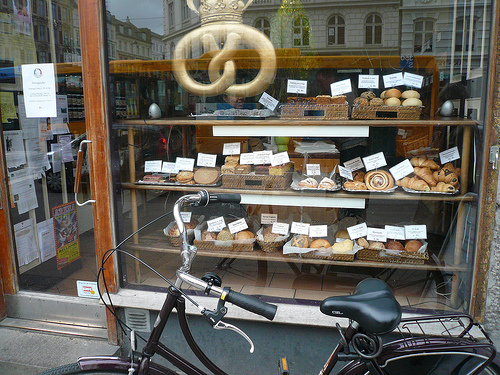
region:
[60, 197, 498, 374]
A bicycle parked in front of the window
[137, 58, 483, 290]
A display of baked goods in the window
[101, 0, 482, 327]
A glass window in front of the baked goods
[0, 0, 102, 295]
A large glass door by the bike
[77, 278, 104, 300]
A small white tag on the door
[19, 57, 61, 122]
A white paper hanging on the glass door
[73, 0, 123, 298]
The glass door has a wooden frame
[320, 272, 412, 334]
Shiny black seat on the bicycle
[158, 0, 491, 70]
A reflection of a stone building in the window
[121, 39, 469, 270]
view is beside acake store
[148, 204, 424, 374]
bicycle is beside the store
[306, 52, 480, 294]
the wall is made of glasses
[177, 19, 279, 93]
the sulpture is light brown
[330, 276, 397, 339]
the bicycle seat is black in color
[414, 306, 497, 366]
the bike is brown in color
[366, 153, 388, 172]
the price tags are white in color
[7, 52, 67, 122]
the poster is white in color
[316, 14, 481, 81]
buldings are seen through the glasses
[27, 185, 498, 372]
a black and chrome bicycle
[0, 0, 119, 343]
a glass entry door with brown wood trim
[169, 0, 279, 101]
a gold pretzel ornament with a crown on top in the window of a shop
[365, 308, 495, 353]
a black wire rack on the back of a bicycle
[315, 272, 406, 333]
a black bicycle seat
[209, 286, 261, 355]
the silver and black brake handle on a bicycle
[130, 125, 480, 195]
a row of various pasteries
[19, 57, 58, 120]
a white sign with black lettering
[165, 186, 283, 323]
chrome and black bicycle handlebars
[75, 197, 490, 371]
dark red bike parked in front of bakery shop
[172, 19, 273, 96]
giant pretzel-shaped decoration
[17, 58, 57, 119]
sign affixed on bakery door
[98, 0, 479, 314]
bakery window displays multiple items for sale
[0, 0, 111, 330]
glass door with wooden frame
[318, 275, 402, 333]
saddle of bike is black and leather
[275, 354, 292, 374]
pedal of bike with reflective rectangle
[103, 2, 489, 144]
window reflects buildings across the street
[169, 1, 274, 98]
pretzel decoration with crown mounted on it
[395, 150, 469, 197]
croissants on plate displayed on shelf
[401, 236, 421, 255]
Small pastry on display in a window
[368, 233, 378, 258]
Small pastry on display in a window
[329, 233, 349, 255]
Small pastry on display in a window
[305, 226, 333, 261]
Small pastry on display in a window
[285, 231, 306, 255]
Small pastry on display in a window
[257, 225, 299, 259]
Small pastry on display in a window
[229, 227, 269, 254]
Small pastry on display in a window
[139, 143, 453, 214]
Small pastry on display in a window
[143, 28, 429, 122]
Small pastry on display in a window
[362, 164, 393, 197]
Small pastry on display in a window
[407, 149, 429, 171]
a pastry on the display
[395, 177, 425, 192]
a pastry on the display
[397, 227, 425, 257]
a pastry on the display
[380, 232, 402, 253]
a pastry on the display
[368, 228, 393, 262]
a pastry on the display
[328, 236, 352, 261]
a pastry on the display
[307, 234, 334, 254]
a pastry on the display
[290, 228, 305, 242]
a pastry on the display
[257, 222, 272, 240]
a pastry on the display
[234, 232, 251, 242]
a pastry on the display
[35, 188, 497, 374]
Bicycle parked in front of the shop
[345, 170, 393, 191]
Cinnamon rolls on display in the window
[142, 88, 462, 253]
Baked goods for sale in the window